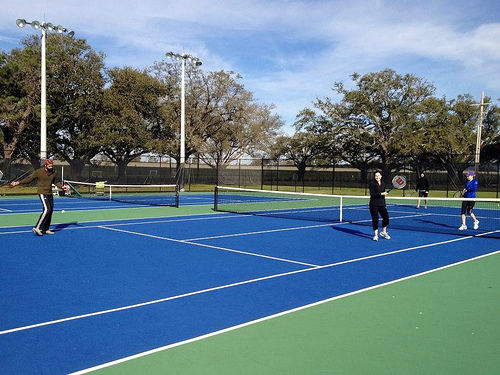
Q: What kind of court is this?
A: Tennis.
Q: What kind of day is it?
A: Sunny.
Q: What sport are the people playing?
A: Tennis.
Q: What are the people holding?
A: Rackets.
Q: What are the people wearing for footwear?
A: Sneakers.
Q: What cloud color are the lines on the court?
A: White.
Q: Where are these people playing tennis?
A: Court.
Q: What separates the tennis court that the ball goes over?
A: Net.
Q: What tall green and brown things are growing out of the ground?
A: Trees.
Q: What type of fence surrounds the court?
A: Chain link.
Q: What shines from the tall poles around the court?
A: Lights.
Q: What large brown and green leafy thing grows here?
A: Tree.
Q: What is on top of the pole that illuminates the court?
A: Lights.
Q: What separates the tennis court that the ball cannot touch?
A: Net.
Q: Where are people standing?
A: On a tennis court.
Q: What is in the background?
A: Trees.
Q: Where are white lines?
A: On the court.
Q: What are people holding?
A: Tennis rackets.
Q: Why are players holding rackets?
A: To hit the tennis ball.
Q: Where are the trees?
A: Behind the fence.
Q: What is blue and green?
A: Tennis court.